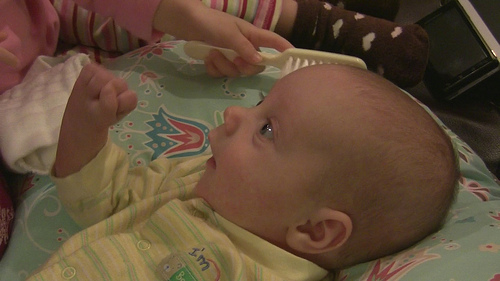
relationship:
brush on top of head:
[185, 39, 366, 76] [195, 61, 457, 269]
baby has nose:
[27, 63, 460, 280] [222, 106, 240, 134]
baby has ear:
[27, 63, 460, 280] [288, 206, 352, 255]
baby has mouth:
[27, 63, 460, 280] [204, 129, 217, 170]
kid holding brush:
[0, 2, 432, 94] [185, 39, 366, 76]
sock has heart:
[289, 2, 427, 89] [363, 33, 376, 51]